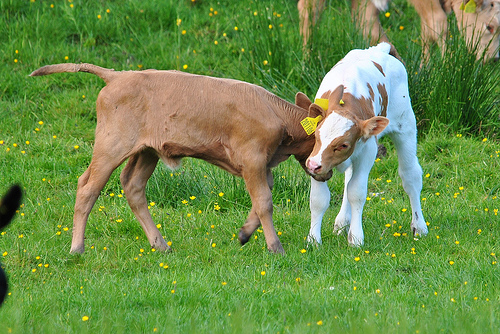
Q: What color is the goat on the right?
A: White.